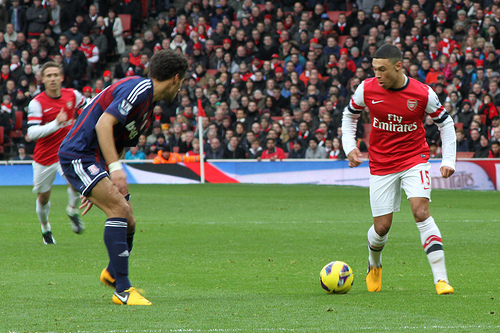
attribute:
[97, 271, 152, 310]
cleats — yellow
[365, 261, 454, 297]
cleats — yellow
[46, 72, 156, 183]
jersey — blue, red